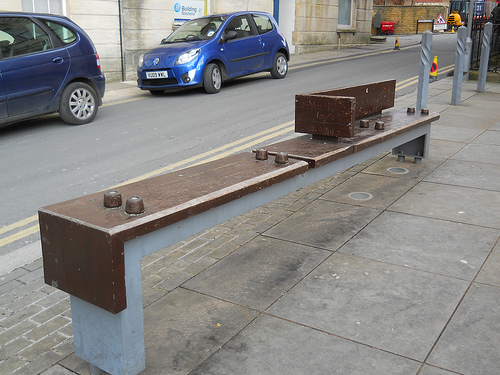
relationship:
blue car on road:
[133, 2, 298, 99] [141, 71, 412, 128]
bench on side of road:
[51, 57, 451, 371] [60, 96, 242, 161]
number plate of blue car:
[143, 69, 170, 79] [136, 10, 291, 95]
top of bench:
[33, 149, 308, 314] [39, 96, 446, 372]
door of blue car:
[223, 13, 266, 78] [136, 10, 291, 95]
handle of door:
[51, 52, 73, 71] [6, 17, 76, 121]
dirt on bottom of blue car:
[2, 98, 57, 124] [0, 10, 106, 127]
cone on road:
[429, 55, 438, 79] [2, 31, 467, 265]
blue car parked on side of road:
[136, 10, 291, 95] [6, 15, 456, 275]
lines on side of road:
[2, 206, 40, 247] [6, 15, 456, 275]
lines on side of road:
[0, 120, 294, 247] [6, 15, 456, 275]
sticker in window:
[205, 29, 215, 36] [160, 15, 225, 42]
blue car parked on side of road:
[136, 10, 291, 95] [2, 31, 467, 265]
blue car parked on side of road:
[136, 10, 291, 95] [101, 93, 229, 158]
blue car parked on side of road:
[136, 10, 291, 95] [10, 117, 180, 178]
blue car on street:
[136, 10, 291, 95] [6, 103, 147, 189]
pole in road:
[414, 25, 436, 131] [0, 33, 500, 375]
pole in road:
[449, 19, 471, 110] [0, 33, 500, 375]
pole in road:
[478, 16, 498, 87] [0, 33, 500, 375]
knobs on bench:
[101, 186, 146, 212] [39, 96, 446, 372]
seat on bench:
[306, 66, 391, 143] [39, 96, 446, 372]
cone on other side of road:
[423, 43, 452, 93] [0, 33, 500, 375]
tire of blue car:
[56, 79, 98, 127] [0, 10, 106, 127]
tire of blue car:
[193, 61, 233, 101] [136, 10, 291, 95]